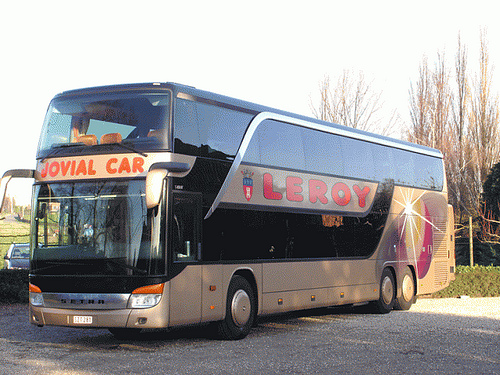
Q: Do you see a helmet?
A: No, there are no helmets.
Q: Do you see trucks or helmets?
A: No, there are no helmets or trucks.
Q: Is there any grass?
A: Yes, there is grass.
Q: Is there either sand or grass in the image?
A: Yes, there is grass.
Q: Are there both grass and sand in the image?
A: No, there is grass but no sand.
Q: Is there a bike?
A: No, there are no bikes.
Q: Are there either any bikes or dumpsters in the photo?
A: No, there are no bikes or dumpsters.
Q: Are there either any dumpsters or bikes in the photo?
A: No, there are no bikes or dumpsters.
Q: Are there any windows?
A: Yes, there is a window.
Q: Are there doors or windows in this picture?
A: Yes, there is a window.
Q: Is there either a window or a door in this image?
A: Yes, there is a window.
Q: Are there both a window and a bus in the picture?
A: Yes, there are both a window and a bus.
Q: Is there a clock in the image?
A: No, there are no clocks.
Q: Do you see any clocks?
A: No, there are no clocks.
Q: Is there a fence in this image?
A: No, there are no fences.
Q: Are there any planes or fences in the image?
A: No, there are no fences or planes.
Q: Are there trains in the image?
A: No, there are no trains.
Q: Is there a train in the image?
A: No, there are no trains.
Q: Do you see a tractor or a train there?
A: No, there are no trains or tractors.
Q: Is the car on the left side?
A: Yes, the car is on the left of the image.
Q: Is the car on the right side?
A: No, the car is on the left of the image.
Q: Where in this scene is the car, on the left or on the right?
A: The car is on the left of the image.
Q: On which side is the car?
A: The car is on the left of the image.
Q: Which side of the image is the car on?
A: The car is on the left of the image.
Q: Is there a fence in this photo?
A: No, there are no fences.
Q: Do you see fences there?
A: No, there are no fences.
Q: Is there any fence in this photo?
A: No, there are no fences.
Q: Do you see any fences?
A: No, there are no fences.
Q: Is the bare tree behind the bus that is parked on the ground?
A: Yes, the tree is behind the bus.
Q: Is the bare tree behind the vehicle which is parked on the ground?
A: Yes, the tree is behind the bus.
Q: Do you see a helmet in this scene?
A: No, there are no helmets.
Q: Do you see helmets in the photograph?
A: No, there are no helmets.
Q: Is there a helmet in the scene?
A: No, there are no helmets.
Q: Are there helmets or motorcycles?
A: No, there are no helmets or motorcycles.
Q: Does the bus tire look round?
A: Yes, the tire is round.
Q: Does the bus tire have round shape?
A: Yes, the tire is round.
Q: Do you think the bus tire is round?
A: Yes, the tire is round.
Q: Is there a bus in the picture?
A: Yes, there is a bus.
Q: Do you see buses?
A: Yes, there is a bus.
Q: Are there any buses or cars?
A: Yes, there is a bus.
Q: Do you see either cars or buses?
A: Yes, there is a bus.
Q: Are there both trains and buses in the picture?
A: No, there is a bus but no trains.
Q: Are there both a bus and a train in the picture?
A: No, there is a bus but no trains.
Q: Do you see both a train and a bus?
A: No, there is a bus but no trains.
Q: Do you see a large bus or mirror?
A: Yes, there is a large bus.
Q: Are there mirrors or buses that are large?
A: Yes, the bus is large.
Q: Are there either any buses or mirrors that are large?
A: Yes, the bus is large.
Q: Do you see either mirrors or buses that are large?
A: Yes, the bus is large.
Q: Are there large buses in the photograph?
A: Yes, there is a large bus.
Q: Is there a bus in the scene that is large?
A: Yes, there is a bus that is large.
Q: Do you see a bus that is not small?
A: Yes, there is a large bus.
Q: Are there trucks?
A: No, there are no trucks.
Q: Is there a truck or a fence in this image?
A: No, there are no trucks or fences.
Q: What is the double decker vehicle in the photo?
A: The vehicle is a bus.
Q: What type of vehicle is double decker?
A: The vehicle is a bus.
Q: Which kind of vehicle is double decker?
A: The vehicle is a bus.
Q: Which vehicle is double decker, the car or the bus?
A: The bus is double decker.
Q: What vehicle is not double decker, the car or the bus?
A: The car is not double decker.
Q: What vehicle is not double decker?
A: The vehicle is a car.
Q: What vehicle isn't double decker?
A: The vehicle is a car.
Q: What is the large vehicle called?
A: The vehicle is a bus.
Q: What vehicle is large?
A: The vehicle is a bus.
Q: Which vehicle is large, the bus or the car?
A: The bus is large.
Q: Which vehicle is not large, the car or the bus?
A: The car is not large.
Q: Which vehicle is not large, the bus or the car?
A: The car is not large.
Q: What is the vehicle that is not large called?
A: The vehicle is a car.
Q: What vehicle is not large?
A: The vehicle is a car.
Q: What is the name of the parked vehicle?
A: The vehicle is a bus.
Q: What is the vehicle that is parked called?
A: The vehicle is a bus.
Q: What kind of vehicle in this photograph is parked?
A: The vehicle is a bus.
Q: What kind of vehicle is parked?
A: The vehicle is a bus.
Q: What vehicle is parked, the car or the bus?
A: The bus is parked.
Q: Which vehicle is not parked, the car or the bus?
A: The car is not parked.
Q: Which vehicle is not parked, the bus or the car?
A: The car is not parked.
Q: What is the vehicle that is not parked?
A: The vehicle is a car.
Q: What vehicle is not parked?
A: The vehicle is a car.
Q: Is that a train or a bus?
A: That is a bus.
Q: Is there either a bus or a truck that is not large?
A: No, there is a bus but it is large.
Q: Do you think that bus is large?
A: Yes, the bus is large.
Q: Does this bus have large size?
A: Yes, the bus is large.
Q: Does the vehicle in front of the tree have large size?
A: Yes, the bus is large.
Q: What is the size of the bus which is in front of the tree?
A: The bus is large.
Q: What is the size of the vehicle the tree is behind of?
A: The bus is large.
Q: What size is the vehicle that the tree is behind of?
A: The bus is large.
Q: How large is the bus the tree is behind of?
A: The bus is large.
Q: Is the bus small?
A: No, the bus is large.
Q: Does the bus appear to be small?
A: No, the bus is large.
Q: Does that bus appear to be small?
A: No, the bus is large.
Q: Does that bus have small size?
A: No, the bus is large.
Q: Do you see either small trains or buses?
A: No, there is a bus but it is large.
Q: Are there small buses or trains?
A: No, there is a bus but it is large.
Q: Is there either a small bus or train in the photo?
A: No, there is a bus but it is large.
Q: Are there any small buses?
A: No, there is a bus but it is large.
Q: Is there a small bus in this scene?
A: No, there is a bus but it is large.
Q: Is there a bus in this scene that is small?
A: No, there is a bus but it is large.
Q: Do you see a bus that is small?
A: No, there is a bus but it is large.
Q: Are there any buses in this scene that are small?
A: No, there is a bus but it is large.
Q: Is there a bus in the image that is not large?
A: No, there is a bus but it is large.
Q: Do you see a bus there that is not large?
A: No, there is a bus but it is large.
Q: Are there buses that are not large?
A: No, there is a bus but it is large.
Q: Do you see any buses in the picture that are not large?
A: No, there is a bus but it is large.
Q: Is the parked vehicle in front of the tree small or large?
A: The bus is large.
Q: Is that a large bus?
A: Yes, that is a large bus.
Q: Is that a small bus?
A: No, that is a large bus.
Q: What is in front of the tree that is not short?
A: The bus is in front of the tree.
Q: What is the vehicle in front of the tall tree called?
A: The vehicle is a bus.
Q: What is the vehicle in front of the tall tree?
A: The vehicle is a bus.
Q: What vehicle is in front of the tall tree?
A: The vehicle is a bus.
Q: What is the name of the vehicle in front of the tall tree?
A: The vehicle is a bus.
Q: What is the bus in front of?
A: The bus is in front of the tree.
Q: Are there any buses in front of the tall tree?
A: Yes, there is a bus in front of the tree.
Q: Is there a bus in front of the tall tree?
A: Yes, there is a bus in front of the tree.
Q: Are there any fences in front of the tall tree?
A: No, there is a bus in front of the tree.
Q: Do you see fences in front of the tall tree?
A: No, there is a bus in front of the tree.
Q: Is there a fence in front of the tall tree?
A: No, there is a bus in front of the tree.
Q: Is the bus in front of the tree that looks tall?
A: Yes, the bus is in front of the tree.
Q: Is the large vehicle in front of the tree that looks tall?
A: Yes, the bus is in front of the tree.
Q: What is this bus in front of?
A: The bus is in front of the tree.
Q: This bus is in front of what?
A: The bus is in front of the tree.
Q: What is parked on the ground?
A: The bus is parked on the ground.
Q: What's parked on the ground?
A: The bus is parked on the ground.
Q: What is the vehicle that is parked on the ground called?
A: The vehicle is a bus.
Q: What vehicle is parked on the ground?
A: The vehicle is a bus.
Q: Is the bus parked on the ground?
A: Yes, the bus is parked on the ground.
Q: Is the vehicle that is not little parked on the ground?
A: Yes, the bus is parked on the ground.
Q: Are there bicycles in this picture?
A: No, there are no bicycles.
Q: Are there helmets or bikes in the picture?
A: No, there are no bikes or helmets.